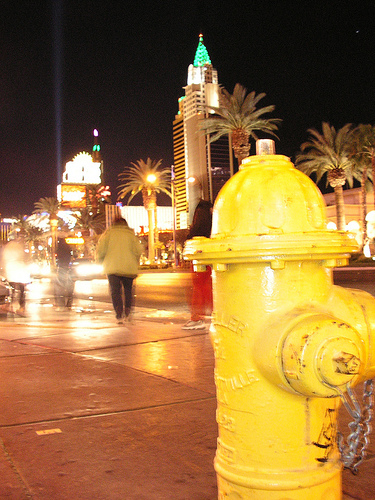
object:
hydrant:
[200, 139, 374, 499]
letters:
[212, 378, 225, 392]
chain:
[337, 381, 374, 477]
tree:
[193, 82, 283, 166]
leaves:
[204, 130, 228, 147]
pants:
[189, 260, 216, 322]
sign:
[62, 152, 102, 185]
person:
[94, 212, 144, 321]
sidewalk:
[0, 292, 374, 500]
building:
[172, 34, 235, 232]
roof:
[193, 33, 212, 69]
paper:
[35, 427, 63, 437]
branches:
[202, 104, 237, 127]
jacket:
[95, 225, 143, 278]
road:
[0, 254, 374, 314]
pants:
[107, 272, 139, 312]